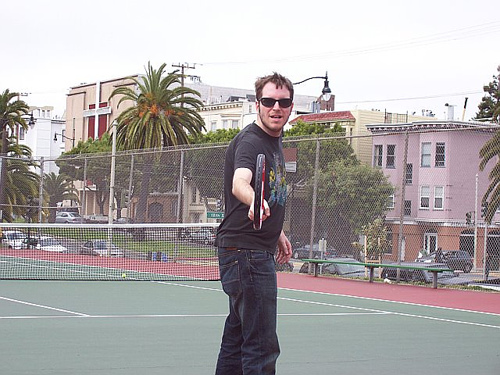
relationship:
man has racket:
[213, 71, 294, 372] [248, 154, 276, 228]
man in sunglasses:
[213, 71, 294, 372] [259, 89, 296, 117]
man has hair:
[213, 71, 294, 372] [257, 72, 293, 101]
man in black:
[213, 71, 294, 372] [219, 126, 300, 364]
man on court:
[215, 71, 292, 372] [0, 126, 500, 375]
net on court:
[0, 220, 221, 281] [0, 126, 500, 375]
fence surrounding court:
[0, 92, 499, 311] [0, 126, 499, 372]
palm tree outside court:
[100, 60, 206, 240] [0, 126, 500, 375]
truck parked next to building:
[389, 263, 472, 292] [364, 117, 498, 272]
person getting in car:
[431, 245, 447, 265] [413, 250, 473, 273]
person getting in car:
[416, 243, 429, 258] [413, 250, 473, 273]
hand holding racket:
[247, 193, 271, 231] [248, 154, 276, 228]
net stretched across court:
[0, 220, 221, 281] [0, 126, 500, 375]